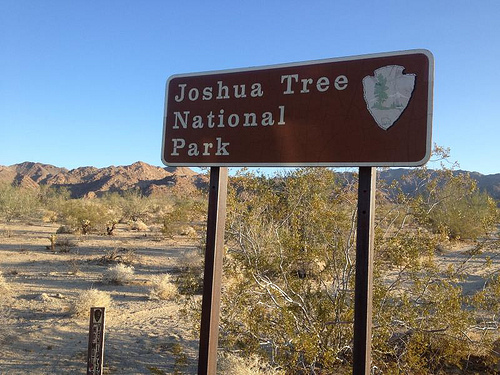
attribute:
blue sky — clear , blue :
[11, 11, 151, 144]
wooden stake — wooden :
[85, 300, 111, 372]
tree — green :
[218, 163, 495, 367]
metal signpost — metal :
[158, 47, 443, 371]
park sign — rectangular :
[155, 50, 433, 166]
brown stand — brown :
[194, 158, 232, 373]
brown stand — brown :
[177, 218, 249, 336]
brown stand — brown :
[172, 213, 252, 333]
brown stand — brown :
[185, 246, 239, 340]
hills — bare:
[12, 155, 182, 195]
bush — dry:
[220, 185, 490, 370]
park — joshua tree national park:
[14, 10, 473, 370]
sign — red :
[155, 59, 445, 165]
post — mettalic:
[82, 314, 110, 373]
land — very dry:
[435, 230, 473, 340]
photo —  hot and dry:
[17, 10, 483, 370]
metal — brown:
[192, 160, 393, 372]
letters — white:
[168, 80, 348, 159]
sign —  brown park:
[154, 58, 433, 178]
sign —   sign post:
[139, 45, 440, 253]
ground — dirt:
[11, 253, 159, 363]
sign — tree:
[140, 17, 448, 370]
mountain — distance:
[11, 141, 179, 205]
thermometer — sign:
[90, 294, 112, 372]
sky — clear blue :
[69, 37, 166, 43]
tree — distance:
[292, 196, 340, 320]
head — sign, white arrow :
[357, 62, 411, 125]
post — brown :
[167, 172, 375, 372]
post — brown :
[169, 156, 398, 368]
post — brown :
[184, 166, 405, 373]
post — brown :
[184, 161, 395, 364]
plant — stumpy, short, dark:
[93, 245, 146, 275]